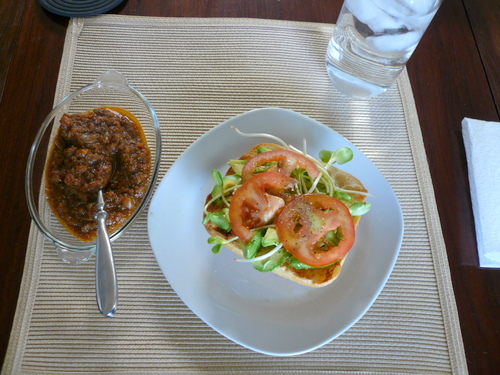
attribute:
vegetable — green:
[202, 149, 372, 276]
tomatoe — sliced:
[276, 194, 355, 268]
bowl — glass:
[21, 61, 159, 264]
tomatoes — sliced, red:
[228, 134, 363, 286]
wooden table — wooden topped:
[0, 0, 499, 374]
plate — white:
[145, 106, 405, 357]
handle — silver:
[92, 189, 121, 316]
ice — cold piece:
[374, 39, 418, 54]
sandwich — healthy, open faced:
[197, 120, 376, 295]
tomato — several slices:
[226, 145, 361, 269]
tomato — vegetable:
[231, 172, 296, 247]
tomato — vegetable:
[239, 148, 324, 191]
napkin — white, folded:
[447, 110, 499, 274]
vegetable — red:
[213, 137, 377, 264]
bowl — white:
[171, 105, 444, 357]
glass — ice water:
[319, 2, 451, 122]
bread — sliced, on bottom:
[140, 105, 419, 302]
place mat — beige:
[7, 4, 474, 374]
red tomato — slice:
[275, 192, 355, 266]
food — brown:
[40, 105, 157, 239]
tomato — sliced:
[229, 173, 295, 243]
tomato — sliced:
[239, 147, 318, 183]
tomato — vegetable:
[275, 191, 357, 266]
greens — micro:
[201, 124, 372, 272]